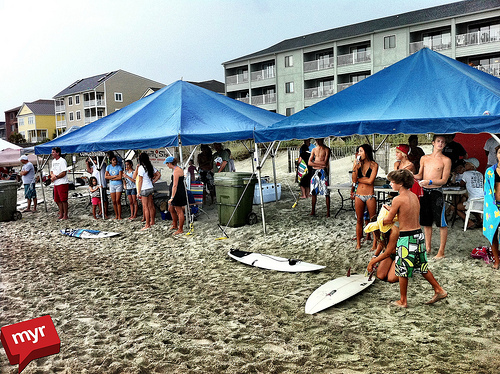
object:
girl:
[136, 150, 160, 230]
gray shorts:
[139, 187, 154, 196]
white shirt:
[137, 165, 153, 190]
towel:
[477, 167, 500, 246]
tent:
[34, 80, 288, 236]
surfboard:
[302, 274, 376, 314]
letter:
[12, 329, 38, 345]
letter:
[27, 327, 38, 345]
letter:
[38, 326, 50, 338]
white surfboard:
[227, 247, 330, 273]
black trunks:
[419, 184, 450, 227]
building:
[218, 0, 499, 224]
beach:
[0, 122, 500, 374]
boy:
[378, 168, 447, 307]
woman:
[394, 144, 416, 175]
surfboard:
[227, 247, 327, 271]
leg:
[355, 195, 365, 246]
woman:
[351, 143, 378, 249]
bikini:
[356, 163, 372, 178]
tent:
[249, 46, 499, 236]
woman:
[370, 214, 399, 284]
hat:
[362, 204, 398, 234]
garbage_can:
[212, 171, 258, 228]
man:
[404, 133, 451, 260]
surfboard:
[58, 228, 124, 239]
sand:
[0, 233, 500, 374]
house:
[0, 99, 55, 143]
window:
[27, 115, 34, 126]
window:
[16, 117, 22, 127]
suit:
[348, 157, 378, 203]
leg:
[167, 203, 178, 230]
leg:
[135, 194, 150, 229]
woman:
[123, 147, 162, 229]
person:
[481, 144, 499, 269]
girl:
[104, 154, 123, 219]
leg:
[387, 260, 399, 284]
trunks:
[394, 228, 430, 278]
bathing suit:
[166, 174, 187, 207]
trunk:
[419, 186, 448, 228]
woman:
[163, 156, 186, 235]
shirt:
[103, 163, 123, 185]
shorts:
[109, 182, 124, 193]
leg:
[376, 257, 393, 281]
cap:
[163, 156, 175, 164]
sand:
[152, 289, 239, 340]